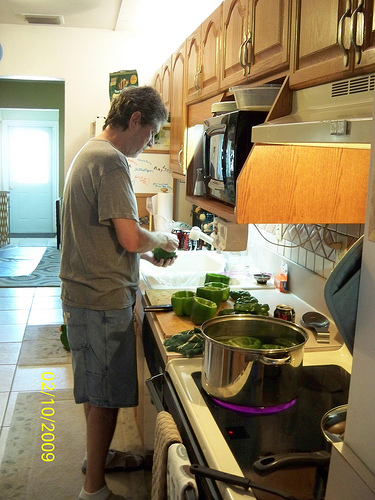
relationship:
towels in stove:
[142, 406, 199, 493] [142, 350, 356, 499]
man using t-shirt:
[53, 79, 184, 492] [55, 137, 150, 314]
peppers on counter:
[164, 266, 258, 316] [151, 260, 340, 370]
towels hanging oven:
[142, 406, 199, 493] [144, 368, 206, 496]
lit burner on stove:
[206, 395, 300, 418] [142, 350, 356, 499]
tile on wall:
[302, 228, 325, 253] [278, 227, 339, 292]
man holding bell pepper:
[53, 79, 184, 492] [151, 238, 177, 266]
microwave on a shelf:
[197, 110, 263, 208] [179, 188, 231, 225]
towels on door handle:
[142, 406, 199, 493] [144, 368, 206, 496]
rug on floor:
[10, 319, 74, 369] [2, 239, 64, 499]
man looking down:
[53, 79, 184, 492] [136, 123, 184, 268]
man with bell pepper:
[53, 79, 184, 492] [151, 238, 177, 266]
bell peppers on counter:
[164, 266, 258, 316] [151, 260, 340, 370]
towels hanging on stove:
[142, 406, 199, 493] [142, 350, 356, 499]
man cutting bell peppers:
[53, 79, 184, 492] [153, 245, 261, 313]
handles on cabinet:
[238, 31, 255, 79] [220, 0, 292, 75]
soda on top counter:
[274, 299, 296, 320] [151, 260, 340, 370]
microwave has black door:
[197, 110, 263, 208] [202, 123, 231, 189]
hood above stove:
[248, 72, 374, 142] [142, 350, 356, 499]